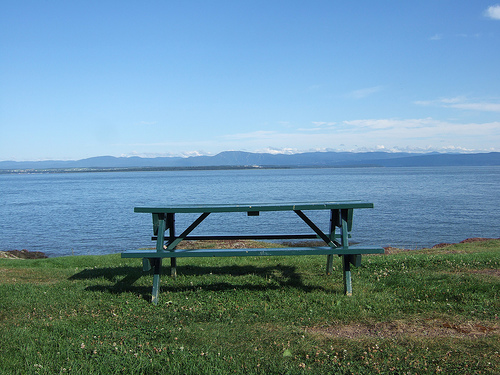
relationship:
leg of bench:
[342, 260, 357, 297] [121, 200, 389, 298]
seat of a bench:
[123, 246, 390, 258] [121, 200, 389, 298]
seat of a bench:
[155, 228, 349, 237] [121, 200, 389, 298]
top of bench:
[134, 200, 377, 216] [121, 200, 389, 298]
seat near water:
[155, 228, 349, 237] [14, 165, 493, 245]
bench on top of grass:
[121, 200, 389, 298] [173, 300, 256, 358]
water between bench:
[14, 165, 493, 245] [121, 200, 389, 298]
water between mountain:
[14, 165, 493, 245] [7, 143, 495, 164]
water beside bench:
[14, 165, 493, 245] [121, 200, 389, 298]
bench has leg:
[121, 200, 389, 298] [147, 211, 167, 301]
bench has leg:
[121, 200, 389, 298] [336, 212, 358, 299]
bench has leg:
[121, 200, 389, 298] [161, 212, 180, 279]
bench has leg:
[121, 200, 389, 298] [324, 202, 343, 278]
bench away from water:
[121, 200, 389, 298] [3, 157, 495, 257]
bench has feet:
[121, 200, 389, 298] [147, 256, 163, 301]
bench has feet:
[121, 200, 389, 298] [338, 257, 354, 297]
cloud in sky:
[319, 107, 498, 129] [2, 2, 495, 152]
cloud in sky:
[230, 129, 497, 153] [2, 2, 495, 152]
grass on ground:
[173, 300, 256, 358] [1, 249, 498, 373]